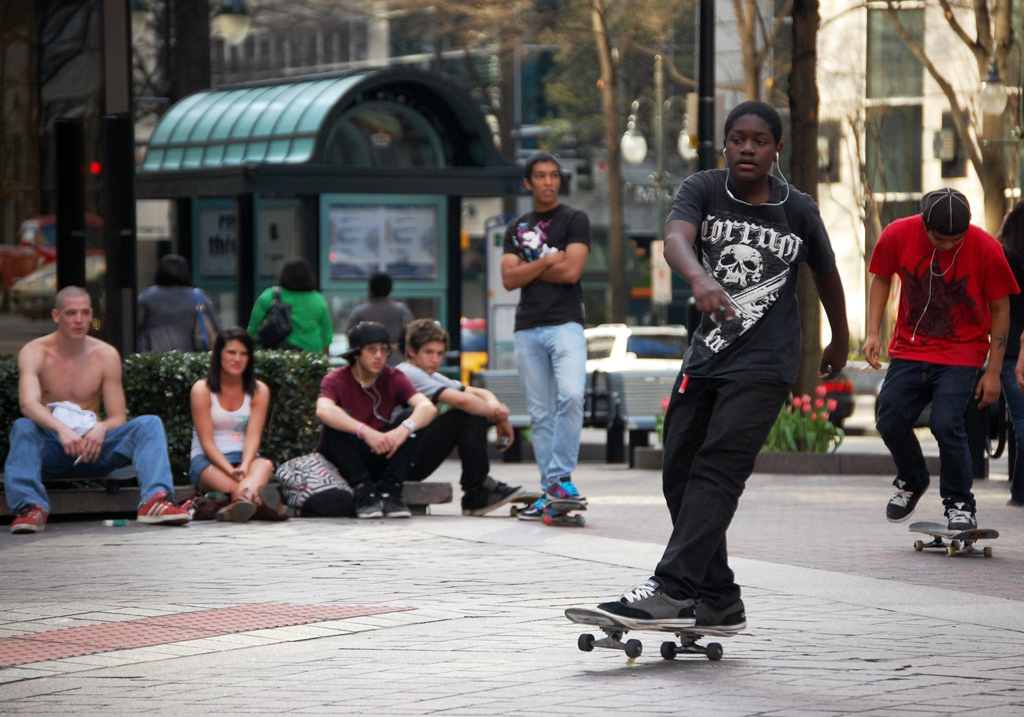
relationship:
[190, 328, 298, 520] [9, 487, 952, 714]
woman sitting floor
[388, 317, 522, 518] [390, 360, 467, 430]
man in shirt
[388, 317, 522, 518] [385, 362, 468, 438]
man in shirt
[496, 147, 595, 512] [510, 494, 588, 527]
man standing on skateboard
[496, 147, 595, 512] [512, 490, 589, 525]
man standing on skateboard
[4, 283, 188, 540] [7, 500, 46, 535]
man wearing shoes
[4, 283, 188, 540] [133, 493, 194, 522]
man wearing shoes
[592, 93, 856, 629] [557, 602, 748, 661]
boy riding skateboard